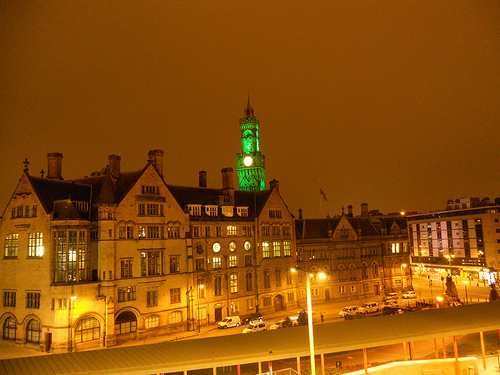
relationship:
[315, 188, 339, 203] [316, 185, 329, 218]
flag on pole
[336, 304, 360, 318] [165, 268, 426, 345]
vehicles on street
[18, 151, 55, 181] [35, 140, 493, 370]
sculptures on building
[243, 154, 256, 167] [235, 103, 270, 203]
clock on clock tower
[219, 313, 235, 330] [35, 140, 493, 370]
van in front of building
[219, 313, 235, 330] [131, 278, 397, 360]
van on roadway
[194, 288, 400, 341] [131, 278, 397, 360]
vehicles on roadway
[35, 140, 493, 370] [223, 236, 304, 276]
building has windows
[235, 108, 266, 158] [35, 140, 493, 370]
steeple on building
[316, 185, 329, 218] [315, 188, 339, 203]
pole and flag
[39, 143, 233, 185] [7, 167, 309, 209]
chimneys on roof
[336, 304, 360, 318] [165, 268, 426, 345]
vehicles in street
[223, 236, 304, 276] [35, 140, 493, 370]
windows in building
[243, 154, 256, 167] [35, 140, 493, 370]
clock in building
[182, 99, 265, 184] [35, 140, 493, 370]
top of building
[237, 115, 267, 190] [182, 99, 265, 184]
light on top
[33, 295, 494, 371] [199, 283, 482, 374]
panel on bridge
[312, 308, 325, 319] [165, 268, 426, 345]
man walking on street